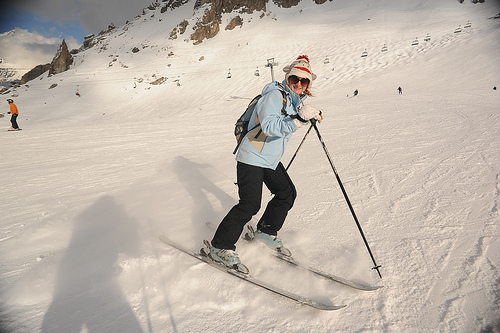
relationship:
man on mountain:
[209, 57, 320, 252] [4, 7, 493, 328]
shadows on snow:
[42, 190, 165, 329] [8, 145, 203, 327]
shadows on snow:
[165, 142, 247, 254] [8, 145, 203, 327]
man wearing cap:
[7, 97, 19, 132] [6, 96, 14, 103]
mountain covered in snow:
[4, 7, 493, 328] [1, 0, 498, 330]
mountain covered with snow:
[4, 7, 493, 328] [1, 0, 498, 330]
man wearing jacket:
[209, 57, 320, 252] [235, 76, 300, 168]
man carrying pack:
[209, 57, 320, 252] [235, 93, 286, 144]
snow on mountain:
[41, 123, 184, 266] [46, 2, 474, 53]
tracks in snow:
[399, 181, 499, 331] [1, 0, 498, 330]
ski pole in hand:
[305, 115, 385, 280] [298, 104, 329, 128]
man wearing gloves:
[209, 57, 320, 252] [296, 92, 319, 121]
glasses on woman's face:
[285, 77, 313, 99] [288, 64, 311, 94]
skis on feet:
[153, 220, 382, 309] [200, 225, 286, 262]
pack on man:
[235, 93, 256, 139] [209, 57, 320, 252]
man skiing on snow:
[7, 97, 19, 127] [351, 111, 463, 204]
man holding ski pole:
[209, 57, 320, 252] [311, 115, 384, 281]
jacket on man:
[232, 78, 307, 172] [209, 57, 320, 252]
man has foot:
[209, 57, 320, 252] [250, 227, 297, 256]